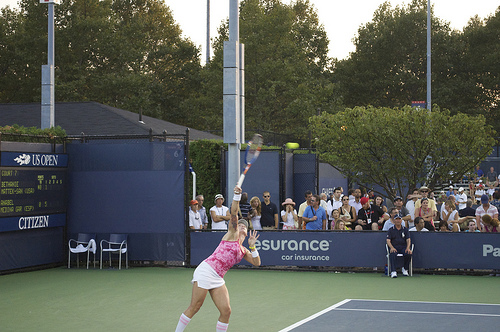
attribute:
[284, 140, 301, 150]
ball — green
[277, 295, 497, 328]
tennis court — blue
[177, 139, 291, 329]
tennis — for a match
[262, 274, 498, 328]
court — for tennis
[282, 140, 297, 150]
ball — for tennis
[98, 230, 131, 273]
chair — metal, plastic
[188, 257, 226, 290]
skirt — white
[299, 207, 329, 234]
shirt — blue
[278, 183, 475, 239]
people — crowd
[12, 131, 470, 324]
match — tennis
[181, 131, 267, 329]
player — tennis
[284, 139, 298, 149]
ball — tennis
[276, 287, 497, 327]
court — tennis, blue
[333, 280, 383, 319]
lines — white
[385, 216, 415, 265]
judge — line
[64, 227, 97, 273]
chair — metal, plastic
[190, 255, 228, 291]
shorts — white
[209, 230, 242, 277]
shirt — pink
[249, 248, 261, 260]
wrist band — white, cloth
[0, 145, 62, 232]
scoreboard — electronic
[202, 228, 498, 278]
fence — metal, plastic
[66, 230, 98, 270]
chair — white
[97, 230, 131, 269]
chair — white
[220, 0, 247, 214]
light pole — tall, metal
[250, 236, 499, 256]
white letters — blue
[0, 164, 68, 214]
scoreboard — tennis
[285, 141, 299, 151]
ball — tennis, yellow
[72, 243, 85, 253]
towel — white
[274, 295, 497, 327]
white lines — tennis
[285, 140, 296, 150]
tennis ball — fluorescent, green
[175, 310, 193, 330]
sock — white, pink, knee high